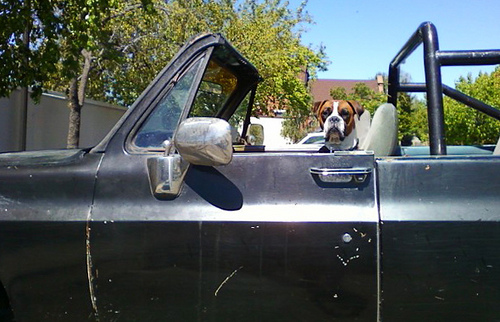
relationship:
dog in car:
[315, 100, 363, 147] [11, 16, 497, 318]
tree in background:
[0, 5, 141, 150] [2, 2, 500, 66]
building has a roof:
[262, 82, 385, 137] [306, 75, 383, 104]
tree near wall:
[0, 5, 141, 150] [3, 82, 129, 157]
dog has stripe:
[315, 100, 363, 147] [324, 101, 344, 135]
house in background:
[262, 82, 385, 137] [2, 2, 500, 66]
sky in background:
[234, 2, 495, 73] [2, 2, 500, 66]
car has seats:
[11, 16, 497, 318] [354, 103, 398, 157]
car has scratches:
[11, 16, 497, 318] [205, 227, 372, 295]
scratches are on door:
[205, 227, 372, 295] [103, 33, 377, 317]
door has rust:
[103, 33, 377, 317] [84, 208, 100, 312]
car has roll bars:
[11, 16, 497, 318] [377, 19, 499, 158]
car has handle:
[11, 16, 497, 318] [309, 163, 373, 178]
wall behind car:
[3, 82, 129, 157] [11, 16, 497, 318]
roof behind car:
[306, 75, 383, 104] [11, 16, 497, 318]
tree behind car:
[0, 5, 141, 150] [11, 16, 497, 318]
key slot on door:
[354, 175, 366, 182] [103, 33, 377, 317]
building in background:
[262, 82, 385, 137] [2, 2, 500, 66]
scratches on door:
[205, 227, 372, 295] [103, 33, 377, 317]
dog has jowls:
[315, 100, 363, 147] [324, 126, 342, 141]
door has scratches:
[103, 33, 377, 317] [205, 227, 372, 295]